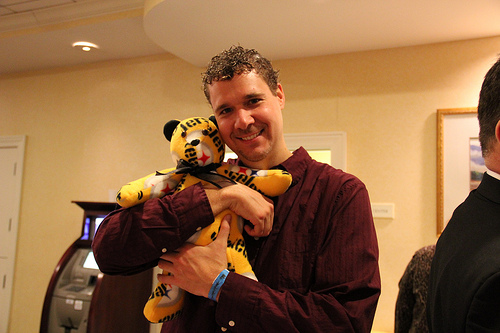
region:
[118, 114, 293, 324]
Yellow and black steelers teddy bear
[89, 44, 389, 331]
Man holding onto teddy bear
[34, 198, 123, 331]
ATM in the background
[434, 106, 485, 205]
Wooden picture frame on wall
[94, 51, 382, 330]
Man in burgundy shirt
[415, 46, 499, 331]
Man in black suit.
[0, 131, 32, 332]
White door in the background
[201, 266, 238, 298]
Blue bracelt on mans wrist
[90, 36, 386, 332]
Man has curly hair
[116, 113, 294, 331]
Steelers teddy bear has black ribbon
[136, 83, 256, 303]
The man is holding a teddy bear.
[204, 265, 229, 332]
A blue band around the man wrist.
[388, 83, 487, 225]
A picture on the wall.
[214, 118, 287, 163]
The man is smiling.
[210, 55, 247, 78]
The man has curly wavy hair.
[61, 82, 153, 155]
The wall is yellow.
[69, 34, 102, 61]
Light on the ceiling.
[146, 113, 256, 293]
The teddy bear is yellow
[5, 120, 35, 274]
The door on the side.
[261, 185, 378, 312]
The man shirt is burgundy.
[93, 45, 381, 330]
man holding a stuffed bear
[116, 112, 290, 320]
yellow and black Steelers stuffed animal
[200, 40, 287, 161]
man has curly brown hair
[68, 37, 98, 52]
round light on the ceiling is on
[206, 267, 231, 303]
blue band on man's wrist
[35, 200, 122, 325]
automatic teller machine against wall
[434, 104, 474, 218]
picture frame is brown and wooden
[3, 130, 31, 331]
silver hinges on white door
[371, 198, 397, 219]
white thermometer on the wall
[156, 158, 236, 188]
black lace bow on bear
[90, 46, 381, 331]
man holding a yellow and black stuffed animal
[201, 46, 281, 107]
man has short, curly, light brown hair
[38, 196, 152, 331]
an ATM machine is along the wall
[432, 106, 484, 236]
an art print is framed in brown wood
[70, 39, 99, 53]
recessed lighting is on the ceiling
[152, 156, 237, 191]
stuffed animal has a black ribbon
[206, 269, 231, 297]
man has a blue event wristband on left wrist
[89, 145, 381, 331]
man is wearing maroon long sleeved shirt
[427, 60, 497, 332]
man on right is wearing black jacket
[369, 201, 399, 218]
thermostat is on wall behind smiling man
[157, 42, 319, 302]
Smiling man hugs teddy bear.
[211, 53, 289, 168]
Brown curly hair 5 o'clock shadow.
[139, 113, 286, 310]
Gold teddy bear black lettering.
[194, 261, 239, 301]
Blue wristband black lettering.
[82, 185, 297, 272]
Right arm long sleeve across bear.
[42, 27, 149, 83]
Round recessed lighting ceiling.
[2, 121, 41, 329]
White wood door left.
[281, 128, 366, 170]
Open doorway behind man.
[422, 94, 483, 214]
Wood framed matted picture wall.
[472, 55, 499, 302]
Person white clothing neck.